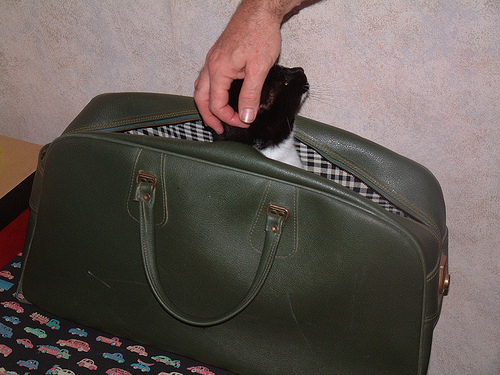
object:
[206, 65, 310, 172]
kitten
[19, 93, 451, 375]
bag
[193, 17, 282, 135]
hand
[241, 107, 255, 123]
fingernail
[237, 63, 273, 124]
thumb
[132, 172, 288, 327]
handle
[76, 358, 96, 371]
car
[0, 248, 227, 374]
cloth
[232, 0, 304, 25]
arm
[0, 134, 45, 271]
box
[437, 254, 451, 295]
buckle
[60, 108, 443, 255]
zipper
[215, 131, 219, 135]
nail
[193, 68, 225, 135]
finger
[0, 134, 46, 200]
table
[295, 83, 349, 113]
whiskers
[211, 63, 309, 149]
head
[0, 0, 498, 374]
wall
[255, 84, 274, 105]
eyes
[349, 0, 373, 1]
body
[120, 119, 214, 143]
checkerboard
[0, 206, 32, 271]
border